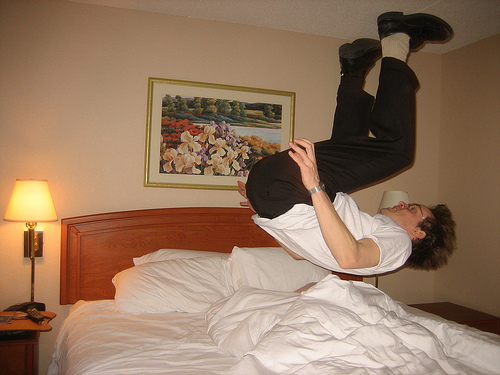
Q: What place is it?
A: It is a hotel room.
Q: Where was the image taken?
A: It was taken at the hotel room.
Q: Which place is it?
A: It is a hotel room.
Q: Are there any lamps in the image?
A: Yes, there is a lamp.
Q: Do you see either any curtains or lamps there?
A: Yes, there is a lamp.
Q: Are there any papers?
A: No, there are no papers.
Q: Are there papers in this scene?
A: No, there are no papers.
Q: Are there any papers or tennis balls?
A: No, there are no papers or tennis balls.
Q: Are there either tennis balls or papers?
A: No, there are no papers or tennis balls.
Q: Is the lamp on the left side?
A: Yes, the lamp is on the left of the image.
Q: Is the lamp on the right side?
A: No, the lamp is on the left of the image.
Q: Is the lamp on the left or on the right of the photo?
A: The lamp is on the left of the image.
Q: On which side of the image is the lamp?
A: The lamp is on the left of the image.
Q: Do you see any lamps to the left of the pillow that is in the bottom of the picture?
A: Yes, there is a lamp to the left of the pillow.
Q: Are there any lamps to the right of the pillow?
A: No, the lamp is to the left of the pillow.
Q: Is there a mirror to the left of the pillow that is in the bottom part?
A: No, there is a lamp to the left of the pillow.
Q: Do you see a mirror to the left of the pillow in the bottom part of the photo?
A: No, there is a lamp to the left of the pillow.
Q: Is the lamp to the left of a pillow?
A: Yes, the lamp is to the left of a pillow.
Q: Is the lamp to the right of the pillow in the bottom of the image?
A: No, the lamp is to the left of the pillow.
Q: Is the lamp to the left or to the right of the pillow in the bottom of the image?
A: The lamp is to the left of the pillow.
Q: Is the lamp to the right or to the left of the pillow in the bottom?
A: The lamp is to the left of the pillow.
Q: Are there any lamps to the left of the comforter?
A: Yes, there is a lamp to the left of the comforter.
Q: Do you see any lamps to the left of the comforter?
A: Yes, there is a lamp to the left of the comforter.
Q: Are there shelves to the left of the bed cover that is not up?
A: No, there is a lamp to the left of the comforter.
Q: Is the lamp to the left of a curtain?
A: No, the lamp is to the left of the bed cover.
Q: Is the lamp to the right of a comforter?
A: No, the lamp is to the left of a comforter.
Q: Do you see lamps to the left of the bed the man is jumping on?
A: Yes, there is a lamp to the left of the bed.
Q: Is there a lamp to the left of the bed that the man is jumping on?
A: Yes, there is a lamp to the left of the bed.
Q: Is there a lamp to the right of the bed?
A: No, the lamp is to the left of the bed.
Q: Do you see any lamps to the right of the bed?
A: No, the lamp is to the left of the bed.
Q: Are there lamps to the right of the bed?
A: No, the lamp is to the left of the bed.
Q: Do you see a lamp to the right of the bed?
A: No, the lamp is to the left of the bed.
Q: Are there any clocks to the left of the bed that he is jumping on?
A: No, there is a lamp to the left of the bed.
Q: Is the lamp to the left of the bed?
A: Yes, the lamp is to the left of the bed.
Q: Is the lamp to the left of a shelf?
A: No, the lamp is to the left of the bed.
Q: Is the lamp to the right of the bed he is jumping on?
A: No, the lamp is to the left of the bed.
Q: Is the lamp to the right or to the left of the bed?
A: The lamp is to the left of the bed.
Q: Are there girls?
A: No, there are no girls.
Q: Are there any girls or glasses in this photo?
A: No, there are no girls or glasses.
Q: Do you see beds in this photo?
A: Yes, there is a bed.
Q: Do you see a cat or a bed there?
A: Yes, there is a bed.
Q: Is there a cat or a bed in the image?
A: Yes, there is a bed.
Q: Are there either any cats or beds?
A: Yes, there is a bed.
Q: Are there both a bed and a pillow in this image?
A: Yes, there are both a bed and a pillow.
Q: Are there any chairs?
A: No, there are no chairs.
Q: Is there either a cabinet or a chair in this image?
A: No, there are no chairs or cabinets.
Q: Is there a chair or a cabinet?
A: No, there are no chairs or cabinets.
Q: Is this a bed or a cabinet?
A: This is a bed.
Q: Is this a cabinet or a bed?
A: This is a bed.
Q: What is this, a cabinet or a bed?
A: This is a bed.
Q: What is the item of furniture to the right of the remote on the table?
A: The piece of furniture is a bed.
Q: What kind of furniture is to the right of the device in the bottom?
A: The piece of furniture is a bed.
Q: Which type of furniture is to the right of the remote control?
A: The piece of furniture is a bed.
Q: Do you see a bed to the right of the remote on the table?
A: Yes, there is a bed to the right of the remote control.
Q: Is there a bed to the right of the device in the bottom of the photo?
A: Yes, there is a bed to the right of the remote control.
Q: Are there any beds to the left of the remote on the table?
A: No, the bed is to the right of the remote.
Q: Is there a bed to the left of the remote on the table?
A: No, the bed is to the right of the remote.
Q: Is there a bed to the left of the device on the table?
A: No, the bed is to the right of the remote.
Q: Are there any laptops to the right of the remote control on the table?
A: No, there is a bed to the right of the remote control.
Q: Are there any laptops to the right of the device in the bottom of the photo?
A: No, there is a bed to the right of the remote control.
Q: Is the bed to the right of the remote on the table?
A: Yes, the bed is to the right of the remote control.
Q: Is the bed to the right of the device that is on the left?
A: Yes, the bed is to the right of the remote control.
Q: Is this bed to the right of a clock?
A: No, the bed is to the right of the remote control.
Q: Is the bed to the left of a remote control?
A: No, the bed is to the right of a remote control.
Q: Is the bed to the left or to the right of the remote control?
A: The bed is to the right of the remote control.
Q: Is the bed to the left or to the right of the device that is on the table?
A: The bed is to the right of the remote control.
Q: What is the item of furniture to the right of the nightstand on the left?
A: The piece of furniture is a bed.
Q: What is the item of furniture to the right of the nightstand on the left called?
A: The piece of furniture is a bed.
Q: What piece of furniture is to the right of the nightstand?
A: The piece of furniture is a bed.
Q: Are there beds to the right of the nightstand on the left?
A: Yes, there is a bed to the right of the nightstand.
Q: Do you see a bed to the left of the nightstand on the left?
A: No, the bed is to the right of the nightstand.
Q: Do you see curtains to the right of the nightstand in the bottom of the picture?
A: No, there is a bed to the right of the nightstand.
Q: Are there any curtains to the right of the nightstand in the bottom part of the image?
A: No, there is a bed to the right of the nightstand.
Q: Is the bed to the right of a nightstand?
A: Yes, the bed is to the right of a nightstand.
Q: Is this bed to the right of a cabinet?
A: No, the bed is to the right of a nightstand.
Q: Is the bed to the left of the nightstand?
A: No, the bed is to the right of the nightstand.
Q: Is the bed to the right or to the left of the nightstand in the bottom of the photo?
A: The bed is to the right of the nightstand.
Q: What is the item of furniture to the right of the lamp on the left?
A: The piece of furniture is a bed.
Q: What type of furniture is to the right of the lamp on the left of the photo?
A: The piece of furniture is a bed.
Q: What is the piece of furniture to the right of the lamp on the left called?
A: The piece of furniture is a bed.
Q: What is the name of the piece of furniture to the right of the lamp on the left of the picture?
A: The piece of furniture is a bed.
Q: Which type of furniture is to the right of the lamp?
A: The piece of furniture is a bed.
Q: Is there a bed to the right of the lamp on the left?
A: Yes, there is a bed to the right of the lamp.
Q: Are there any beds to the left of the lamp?
A: No, the bed is to the right of the lamp.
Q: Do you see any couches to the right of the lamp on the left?
A: No, there is a bed to the right of the lamp.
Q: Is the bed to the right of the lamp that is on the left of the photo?
A: Yes, the bed is to the right of the lamp.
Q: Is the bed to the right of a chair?
A: No, the bed is to the right of the lamp.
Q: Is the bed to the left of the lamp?
A: No, the bed is to the right of the lamp.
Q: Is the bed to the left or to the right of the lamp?
A: The bed is to the right of the lamp.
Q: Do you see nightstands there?
A: Yes, there is a nightstand.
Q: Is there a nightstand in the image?
A: Yes, there is a nightstand.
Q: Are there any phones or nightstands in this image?
A: Yes, there is a nightstand.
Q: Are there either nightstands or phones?
A: Yes, there is a nightstand.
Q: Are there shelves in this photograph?
A: No, there are no shelves.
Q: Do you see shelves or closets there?
A: No, there are no shelves or closets.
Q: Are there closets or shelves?
A: No, there are no shelves or closets.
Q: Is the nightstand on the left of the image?
A: Yes, the nightstand is on the left of the image.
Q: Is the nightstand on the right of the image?
A: No, the nightstand is on the left of the image.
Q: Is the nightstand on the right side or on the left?
A: The nightstand is on the left of the image.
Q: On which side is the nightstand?
A: The nightstand is on the left of the image.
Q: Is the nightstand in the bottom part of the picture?
A: Yes, the nightstand is in the bottom of the image.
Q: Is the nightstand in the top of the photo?
A: No, the nightstand is in the bottom of the image.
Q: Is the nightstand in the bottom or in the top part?
A: The nightstand is in the bottom of the image.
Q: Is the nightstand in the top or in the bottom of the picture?
A: The nightstand is in the bottom of the image.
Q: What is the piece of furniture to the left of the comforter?
A: The piece of furniture is a nightstand.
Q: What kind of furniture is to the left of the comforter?
A: The piece of furniture is a nightstand.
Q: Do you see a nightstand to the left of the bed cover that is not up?
A: Yes, there is a nightstand to the left of the quilt.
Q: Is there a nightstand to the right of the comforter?
A: No, the nightstand is to the left of the comforter.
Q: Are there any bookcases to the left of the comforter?
A: No, there is a nightstand to the left of the comforter.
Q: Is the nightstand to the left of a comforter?
A: Yes, the nightstand is to the left of a comforter.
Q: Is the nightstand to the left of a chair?
A: No, the nightstand is to the left of a comforter.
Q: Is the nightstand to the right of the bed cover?
A: No, the nightstand is to the left of the bed cover.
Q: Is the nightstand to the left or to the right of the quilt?
A: The nightstand is to the left of the quilt.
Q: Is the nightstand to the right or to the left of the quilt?
A: The nightstand is to the left of the quilt.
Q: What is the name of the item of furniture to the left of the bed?
A: The piece of furniture is a nightstand.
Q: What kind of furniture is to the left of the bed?
A: The piece of furniture is a nightstand.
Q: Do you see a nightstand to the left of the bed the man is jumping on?
A: Yes, there is a nightstand to the left of the bed.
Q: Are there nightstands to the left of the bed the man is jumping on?
A: Yes, there is a nightstand to the left of the bed.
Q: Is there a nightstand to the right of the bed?
A: No, the nightstand is to the left of the bed.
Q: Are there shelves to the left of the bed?
A: No, there is a nightstand to the left of the bed.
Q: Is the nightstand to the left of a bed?
A: Yes, the nightstand is to the left of a bed.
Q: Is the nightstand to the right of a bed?
A: No, the nightstand is to the left of a bed.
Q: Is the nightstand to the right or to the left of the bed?
A: The nightstand is to the left of the bed.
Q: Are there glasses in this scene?
A: No, there are no glasses.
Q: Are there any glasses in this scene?
A: No, there are no glasses.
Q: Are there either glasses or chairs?
A: No, there are no glasses or chairs.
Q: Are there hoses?
A: No, there are no hoses.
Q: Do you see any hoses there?
A: No, there are no hoses.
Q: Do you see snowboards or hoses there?
A: No, there are no hoses or snowboards.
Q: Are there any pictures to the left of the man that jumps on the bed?
A: Yes, there is a picture to the left of the man.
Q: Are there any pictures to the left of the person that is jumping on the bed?
A: Yes, there is a picture to the left of the man.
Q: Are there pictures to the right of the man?
A: No, the picture is to the left of the man.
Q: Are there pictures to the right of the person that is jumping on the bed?
A: No, the picture is to the left of the man.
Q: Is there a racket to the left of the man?
A: No, there is a picture to the left of the man.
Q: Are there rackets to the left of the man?
A: No, there is a picture to the left of the man.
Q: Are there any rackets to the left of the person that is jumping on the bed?
A: No, there is a picture to the left of the man.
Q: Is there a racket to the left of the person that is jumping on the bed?
A: No, there is a picture to the left of the man.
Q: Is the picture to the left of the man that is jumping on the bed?
A: Yes, the picture is to the left of the man.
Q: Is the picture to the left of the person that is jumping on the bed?
A: Yes, the picture is to the left of the man.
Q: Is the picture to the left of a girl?
A: No, the picture is to the left of the man.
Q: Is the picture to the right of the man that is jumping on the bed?
A: No, the picture is to the left of the man.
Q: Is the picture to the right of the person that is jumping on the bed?
A: No, the picture is to the left of the man.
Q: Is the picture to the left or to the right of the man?
A: The picture is to the left of the man.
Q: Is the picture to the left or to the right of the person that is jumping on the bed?
A: The picture is to the left of the man.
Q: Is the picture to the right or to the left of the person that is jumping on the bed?
A: The picture is to the left of the man.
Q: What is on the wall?
A: The picture is on the wall.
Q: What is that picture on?
A: The picture is on the wall.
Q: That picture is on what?
A: The picture is on the wall.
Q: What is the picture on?
A: The picture is on the wall.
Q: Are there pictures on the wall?
A: Yes, there is a picture on the wall.